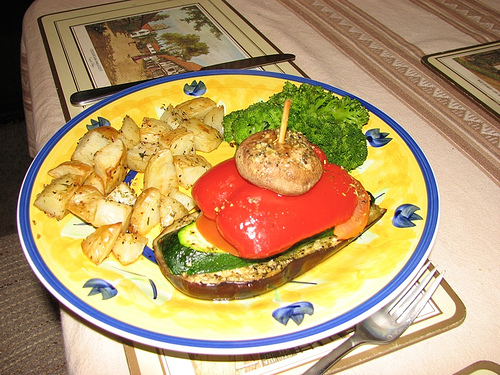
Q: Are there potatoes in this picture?
A: Yes, there is a potato.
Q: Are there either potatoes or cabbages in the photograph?
A: Yes, there is a potato.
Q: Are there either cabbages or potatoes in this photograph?
A: Yes, there is a potato.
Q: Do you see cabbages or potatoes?
A: Yes, there is a potato.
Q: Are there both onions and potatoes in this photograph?
A: No, there is a potato but no onions.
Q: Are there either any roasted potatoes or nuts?
A: Yes, there is a roasted potato.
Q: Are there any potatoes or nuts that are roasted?
A: Yes, the potato is roasted.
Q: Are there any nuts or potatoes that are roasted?
A: Yes, the potato is roasted.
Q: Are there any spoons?
A: No, there are no spoons.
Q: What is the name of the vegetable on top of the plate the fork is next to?
A: The vegetable is a potato.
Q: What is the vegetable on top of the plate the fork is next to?
A: The vegetable is a potato.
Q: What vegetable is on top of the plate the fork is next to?
A: The vegetable is a potato.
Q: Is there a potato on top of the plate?
A: Yes, there is a potato on top of the plate.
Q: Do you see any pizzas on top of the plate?
A: No, there is a potato on top of the plate.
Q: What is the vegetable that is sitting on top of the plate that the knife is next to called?
A: The vegetable is a potato.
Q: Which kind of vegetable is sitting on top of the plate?
A: The vegetable is a potato.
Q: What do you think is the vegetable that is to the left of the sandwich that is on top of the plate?
A: The vegetable is a potato.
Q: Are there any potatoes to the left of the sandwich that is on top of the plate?
A: Yes, there is a potato to the left of the sandwich.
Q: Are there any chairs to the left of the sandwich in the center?
A: No, there is a potato to the left of the sandwich.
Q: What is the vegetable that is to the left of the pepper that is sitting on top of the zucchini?
A: The vegetable is a potato.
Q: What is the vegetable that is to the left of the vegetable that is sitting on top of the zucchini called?
A: The vegetable is a potato.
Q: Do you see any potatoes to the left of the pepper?
A: Yes, there is a potato to the left of the pepper.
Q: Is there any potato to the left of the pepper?
A: Yes, there is a potato to the left of the pepper.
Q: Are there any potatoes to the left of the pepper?
A: Yes, there is a potato to the left of the pepper.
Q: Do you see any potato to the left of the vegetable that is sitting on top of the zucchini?
A: Yes, there is a potato to the left of the pepper.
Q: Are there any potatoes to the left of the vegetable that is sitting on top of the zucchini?
A: Yes, there is a potato to the left of the pepper.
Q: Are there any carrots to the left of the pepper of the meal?
A: No, there is a potato to the left of the pepper.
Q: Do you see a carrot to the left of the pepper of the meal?
A: No, there is a potato to the left of the pepper.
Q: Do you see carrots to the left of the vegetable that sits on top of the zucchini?
A: No, there is a potato to the left of the pepper.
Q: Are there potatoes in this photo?
A: Yes, there is a potato.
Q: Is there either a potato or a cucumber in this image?
A: Yes, there is a potato.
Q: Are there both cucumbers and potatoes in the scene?
A: No, there is a potato but no cucumbers.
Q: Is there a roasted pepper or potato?
A: Yes, there is a roasted potato.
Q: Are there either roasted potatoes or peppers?
A: Yes, there is a roasted potato.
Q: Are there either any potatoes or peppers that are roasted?
A: Yes, the potato is roasted.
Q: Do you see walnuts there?
A: No, there are no walnuts.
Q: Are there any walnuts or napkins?
A: No, there are no walnuts or napkins.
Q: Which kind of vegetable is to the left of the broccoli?
A: The vegetable is a potato.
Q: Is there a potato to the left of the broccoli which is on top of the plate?
A: Yes, there is a potato to the left of the broccoli.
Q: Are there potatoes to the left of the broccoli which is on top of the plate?
A: Yes, there is a potato to the left of the broccoli.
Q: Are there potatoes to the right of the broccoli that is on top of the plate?
A: No, the potato is to the left of the broccoli.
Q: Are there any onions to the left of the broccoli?
A: No, there is a potato to the left of the broccoli.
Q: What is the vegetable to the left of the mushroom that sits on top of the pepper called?
A: The vegetable is a potato.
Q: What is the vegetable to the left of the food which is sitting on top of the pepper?
A: The vegetable is a potato.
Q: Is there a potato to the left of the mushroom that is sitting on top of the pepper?
A: Yes, there is a potato to the left of the mushroom.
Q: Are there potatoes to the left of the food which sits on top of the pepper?
A: Yes, there is a potato to the left of the mushroom.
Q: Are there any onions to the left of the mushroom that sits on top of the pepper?
A: No, there is a potato to the left of the mushroom.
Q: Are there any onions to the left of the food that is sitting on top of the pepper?
A: No, there is a potato to the left of the mushroom.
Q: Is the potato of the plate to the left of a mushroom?
A: Yes, the potato is to the left of a mushroom.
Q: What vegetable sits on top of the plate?
A: The vegetable is a potato.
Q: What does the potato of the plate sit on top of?
A: The potato sits on top of the plate.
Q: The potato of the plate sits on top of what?
A: The potato sits on top of the plate.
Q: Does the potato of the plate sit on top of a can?
A: No, the potato sits on top of a plate.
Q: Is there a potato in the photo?
A: Yes, there is a potato.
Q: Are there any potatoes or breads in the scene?
A: Yes, there is a potato.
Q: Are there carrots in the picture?
A: No, there are no carrots.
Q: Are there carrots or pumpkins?
A: No, there are no carrots or pumpkins.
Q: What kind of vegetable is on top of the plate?
A: The vegetable is a potato.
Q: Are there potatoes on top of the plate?
A: Yes, there is a potato on top of the plate.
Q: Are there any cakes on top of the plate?
A: No, there is a potato on top of the plate.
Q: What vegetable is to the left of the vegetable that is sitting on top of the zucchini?
A: The vegetable is a potato.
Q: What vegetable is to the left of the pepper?
A: The vegetable is a potato.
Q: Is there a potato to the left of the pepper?
A: Yes, there is a potato to the left of the pepper.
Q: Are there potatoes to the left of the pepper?
A: Yes, there is a potato to the left of the pepper.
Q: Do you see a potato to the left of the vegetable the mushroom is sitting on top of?
A: Yes, there is a potato to the left of the pepper.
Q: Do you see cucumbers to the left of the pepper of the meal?
A: No, there is a potato to the left of the pepper.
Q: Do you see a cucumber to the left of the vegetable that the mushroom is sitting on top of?
A: No, there is a potato to the left of the pepper.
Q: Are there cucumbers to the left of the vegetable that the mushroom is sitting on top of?
A: No, there is a potato to the left of the pepper.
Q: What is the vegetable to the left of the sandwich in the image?
A: The vegetable is a potato.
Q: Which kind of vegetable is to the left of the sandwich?
A: The vegetable is a potato.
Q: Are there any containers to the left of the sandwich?
A: No, there is a potato to the left of the sandwich.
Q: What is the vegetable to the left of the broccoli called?
A: The vegetable is a potato.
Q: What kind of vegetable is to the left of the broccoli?
A: The vegetable is a potato.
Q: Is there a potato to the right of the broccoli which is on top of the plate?
A: No, the potato is to the left of the broccoli.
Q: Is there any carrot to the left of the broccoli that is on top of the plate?
A: No, there is a potato to the left of the broccoli.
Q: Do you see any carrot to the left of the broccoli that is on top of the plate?
A: No, there is a potato to the left of the broccoli.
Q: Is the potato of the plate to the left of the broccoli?
A: Yes, the potato is to the left of the broccoli.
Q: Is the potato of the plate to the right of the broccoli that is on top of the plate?
A: No, the potato is to the left of the broccoli.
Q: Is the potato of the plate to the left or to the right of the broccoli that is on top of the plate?
A: The potato is to the left of the broccoli.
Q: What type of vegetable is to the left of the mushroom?
A: The vegetable is a potato.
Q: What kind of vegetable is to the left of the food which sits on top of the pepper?
A: The vegetable is a potato.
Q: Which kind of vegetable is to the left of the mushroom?
A: The vegetable is a potato.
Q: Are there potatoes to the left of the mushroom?
A: Yes, there is a potato to the left of the mushroom.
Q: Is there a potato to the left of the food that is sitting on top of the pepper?
A: Yes, there is a potato to the left of the mushroom.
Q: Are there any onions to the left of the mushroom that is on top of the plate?
A: No, there is a potato to the left of the mushroom.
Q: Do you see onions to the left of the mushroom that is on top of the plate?
A: No, there is a potato to the left of the mushroom.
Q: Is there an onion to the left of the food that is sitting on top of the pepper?
A: No, there is a potato to the left of the mushroom.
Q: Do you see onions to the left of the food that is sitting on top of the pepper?
A: No, there is a potato to the left of the mushroom.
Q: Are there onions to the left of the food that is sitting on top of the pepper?
A: No, there is a potato to the left of the mushroom.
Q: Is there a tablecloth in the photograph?
A: Yes, there is a tablecloth.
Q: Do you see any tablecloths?
A: Yes, there is a tablecloth.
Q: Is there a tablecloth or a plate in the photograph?
A: Yes, there is a tablecloth.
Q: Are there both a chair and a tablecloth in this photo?
A: No, there is a tablecloth but no chairs.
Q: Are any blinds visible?
A: No, there are no blinds.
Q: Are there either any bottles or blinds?
A: No, there are no blinds or bottles.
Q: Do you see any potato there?
A: Yes, there is a potato.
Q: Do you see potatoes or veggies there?
A: Yes, there is a potato.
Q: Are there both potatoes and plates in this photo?
A: Yes, there are both a potato and a plate.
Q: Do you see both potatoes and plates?
A: Yes, there are both a potato and a plate.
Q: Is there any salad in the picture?
A: No, there is no salad.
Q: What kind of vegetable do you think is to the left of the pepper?
A: The vegetable is a potato.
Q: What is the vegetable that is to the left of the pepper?
A: The vegetable is a potato.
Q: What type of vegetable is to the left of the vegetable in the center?
A: The vegetable is a potato.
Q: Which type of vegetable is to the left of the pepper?
A: The vegetable is a potato.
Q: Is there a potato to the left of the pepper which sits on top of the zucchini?
A: Yes, there is a potato to the left of the pepper.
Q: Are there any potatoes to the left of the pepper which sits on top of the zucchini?
A: Yes, there is a potato to the left of the pepper.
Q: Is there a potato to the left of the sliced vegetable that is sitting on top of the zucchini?
A: Yes, there is a potato to the left of the pepper.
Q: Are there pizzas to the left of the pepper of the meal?
A: No, there is a potato to the left of the pepper.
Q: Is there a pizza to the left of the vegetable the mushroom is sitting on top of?
A: No, there is a potato to the left of the pepper.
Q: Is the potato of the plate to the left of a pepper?
A: Yes, the potato is to the left of a pepper.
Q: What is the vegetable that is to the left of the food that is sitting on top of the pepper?
A: The vegetable is a potato.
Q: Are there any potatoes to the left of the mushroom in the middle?
A: Yes, there is a potato to the left of the mushroom.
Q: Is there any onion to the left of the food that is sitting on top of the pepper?
A: No, there is a potato to the left of the mushroom.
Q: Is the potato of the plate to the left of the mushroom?
A: Yes, the potato is to the left of the mushroom.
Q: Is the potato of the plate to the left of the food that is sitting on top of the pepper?
A: Yes, the potato is to the left of the mushroom.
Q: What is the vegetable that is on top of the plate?
A: The vegetable is a potato.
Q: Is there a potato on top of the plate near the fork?
A: Yes, there is a potato on top of the plate.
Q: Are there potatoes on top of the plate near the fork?
A: Yes, there is a potato on top of the plate.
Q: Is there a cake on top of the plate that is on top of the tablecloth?
A: No, there is a potato on top of the plate.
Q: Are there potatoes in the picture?
A: Yes, there is a potato.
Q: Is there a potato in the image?
A: Yes, there is a potato.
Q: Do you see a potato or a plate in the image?
A: Yes, there is a potato.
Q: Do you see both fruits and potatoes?
A: No, there is a potato but no fruits.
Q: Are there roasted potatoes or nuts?
A: Yes, there is a roasted potato.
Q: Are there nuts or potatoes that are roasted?
A: Yes, the potato is roasted.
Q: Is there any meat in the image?
A: No, there is no meat.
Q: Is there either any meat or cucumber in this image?
A: No, there are no meat or cucumbers.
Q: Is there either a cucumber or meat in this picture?
A: No, there are no meat or cucumbers.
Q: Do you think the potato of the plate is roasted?
A: Yes, the potato is roasted.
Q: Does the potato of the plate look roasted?
A: Yes, the potato is roasted.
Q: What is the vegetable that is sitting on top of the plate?
A: The vegetable is a potato.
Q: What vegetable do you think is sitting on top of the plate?
A: The vegetable is a potato.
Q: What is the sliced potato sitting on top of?
A: The potato is sitting on top of the plate.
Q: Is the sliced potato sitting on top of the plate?
A: Yes, the potato is sitting on top of the plate.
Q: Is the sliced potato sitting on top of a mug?
A: No, the potato is sitting on top of the plate.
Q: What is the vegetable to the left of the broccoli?
A: The vegetable is a potato.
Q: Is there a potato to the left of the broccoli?
A: Yes, there is a potato to the left of the broccoli.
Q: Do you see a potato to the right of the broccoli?
A: No, the potato is to the left of the broccoli.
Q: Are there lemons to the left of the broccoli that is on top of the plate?
A: No, there is a potato to the left of the broccoli.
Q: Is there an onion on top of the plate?
A: No, there is a potato on top of the plate.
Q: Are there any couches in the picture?
A: No, there are no couches.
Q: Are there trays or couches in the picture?
A: No, there are no couches or trays.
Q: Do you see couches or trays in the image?
A: No, there are no couches or trays.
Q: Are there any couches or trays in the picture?
A: No, there are no couches or trays.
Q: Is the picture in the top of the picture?
A: Yes, the picture is in the top of the image.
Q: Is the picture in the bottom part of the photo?
A: No, the picture is in the top of the image.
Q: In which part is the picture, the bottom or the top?
A: The picture is in the top of the image.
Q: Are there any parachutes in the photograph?
A: No, there are no parachutes.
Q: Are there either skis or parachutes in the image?
A: No, there are no parachutes or skis.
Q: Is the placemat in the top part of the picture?
A: Yes, the placemat is in the top of the image.